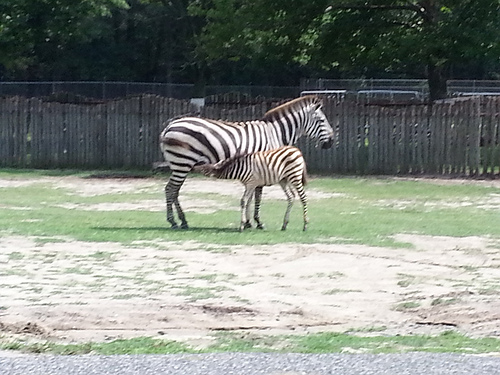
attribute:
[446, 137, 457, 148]
ground — white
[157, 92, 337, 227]
zebra — big, black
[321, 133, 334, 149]
nose — black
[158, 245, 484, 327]
sand — brown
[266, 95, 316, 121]
mane — stiff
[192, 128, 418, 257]
baby zebra — small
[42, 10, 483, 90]
trees — partial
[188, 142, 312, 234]
zebra — baby, small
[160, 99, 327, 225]
fur — black, white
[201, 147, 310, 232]
zebra — small, baby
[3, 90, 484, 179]
fence — wood